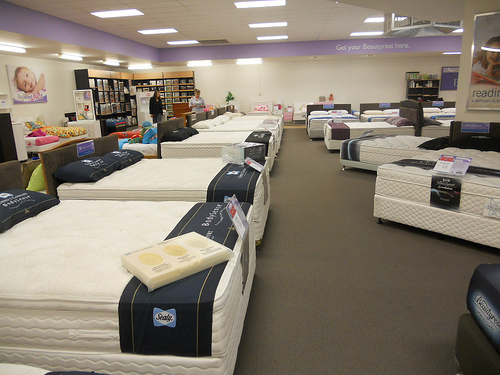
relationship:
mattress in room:
[368, 145, 498, 262] [239, 103, 491, 364]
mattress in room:
[311, 97, 500, 250] [239, 103, 491, 364]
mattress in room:
[0, 190, 255, 358] [239, 103, 491, 364]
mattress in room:
[0, 108, 281, 357] [239, 103, 491, 364]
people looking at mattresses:
[150, 88, 205, 123] [4, 129, 258, 364]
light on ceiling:
[363, 16, 408, 23] [4, 0, 497, 57]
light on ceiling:
[86, 3, 145, 24] [4, 0, 497, 57]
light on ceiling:
[133, 28, 181, 38] [4, 0, 497, 57]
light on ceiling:
[163, 37, 202, 48] [4, 0, 497, 57]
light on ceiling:
[257, 34, 290, 45] [4, 0, 497, 57]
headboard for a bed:
[33, 127, 123, 197] [32, 127, 272, 244]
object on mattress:
[118, 227, 236, 291] [0, 190, 255, 358]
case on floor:
[71, 72, 215, 134] [227, 117, 481, 358]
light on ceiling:
[93, 9, 142, 20] [21, 0, 439, 40]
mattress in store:
[311, 97, 500, 250] [8, 15, 484, 365]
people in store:
[147, 88, 164, 123] [8, 15, 484, 365]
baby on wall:
[11, 67, 48, 102] [2, 51, 92, 152]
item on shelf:
[98, 101, 109, 116] [75, 65, 142, 142]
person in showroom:
[147, 90, 167, 127] [2, 1, 499, 373]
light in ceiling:
[363, 16, 408, 23] [183, 5, 358, 64]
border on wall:
[326, 37, 451, 52] [182, 50, 474, 118]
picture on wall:
[4, 62, 49, 104] [171, 58, 468, 108]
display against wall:
[68, 69, 205, 123] [171, 58, 468, 108]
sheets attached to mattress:
[17, 112, 297, 360] [0, 190, 255, 358]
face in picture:
[21, 70, 38, 107] [4, 62, 49, 104]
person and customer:
[150, 90, 165, 125] [183, 84, 212, 114]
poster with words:
[418, 34, 498, 125] [153, 314, 175, 322]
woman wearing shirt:
[185, 87, 207, 114] [185, 93, 212, 112]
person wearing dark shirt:
[150, 90, 165, 125] [147, 89, 167, 118]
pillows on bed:
[174, 124, 251, 182] [54, 115, 279, 188]